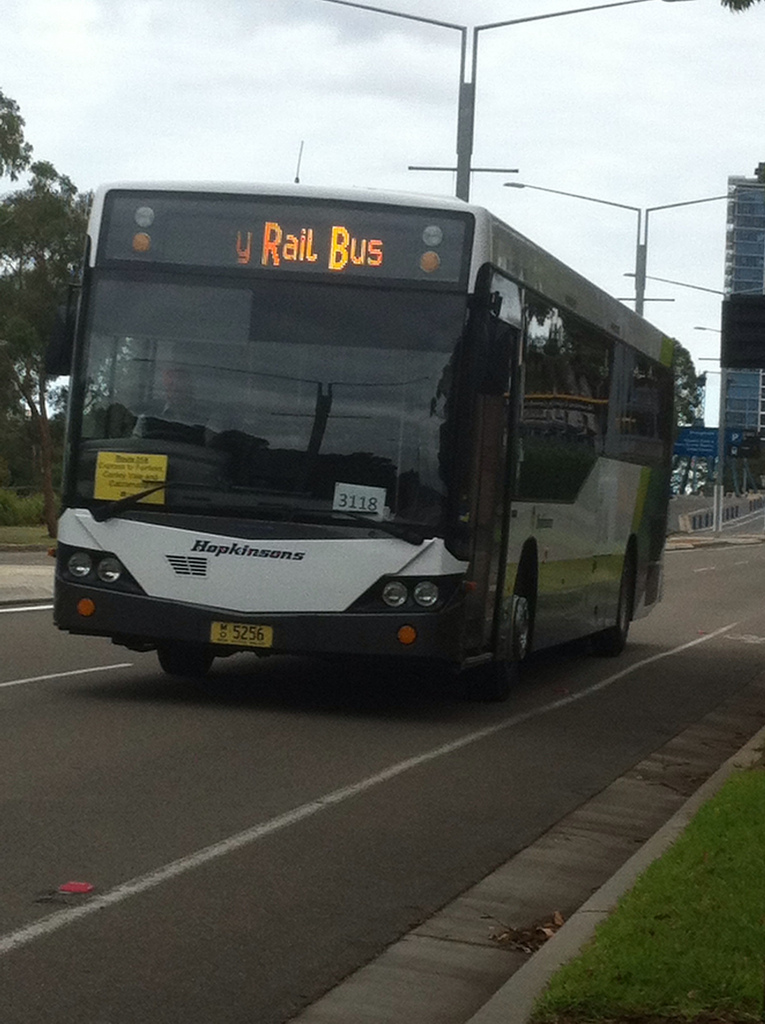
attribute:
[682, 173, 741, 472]
building — wall , side 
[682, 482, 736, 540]
rail — word , signage 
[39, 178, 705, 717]
bus — word , sign , front wheel, rear wheel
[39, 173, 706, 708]
vehicle — license plate